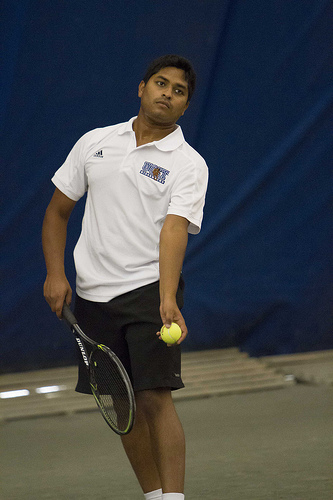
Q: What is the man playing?
A: Tennis.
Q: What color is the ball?
A: Yellow.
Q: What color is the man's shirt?
A: White.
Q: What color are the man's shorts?
A: Black.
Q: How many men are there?
A: One.